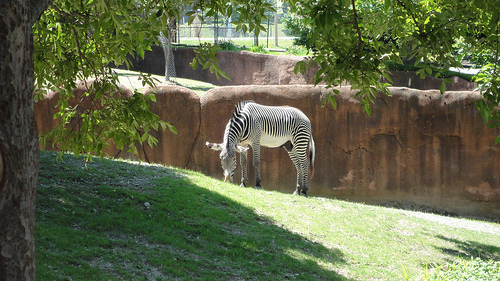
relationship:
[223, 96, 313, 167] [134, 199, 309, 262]
zebra on grass